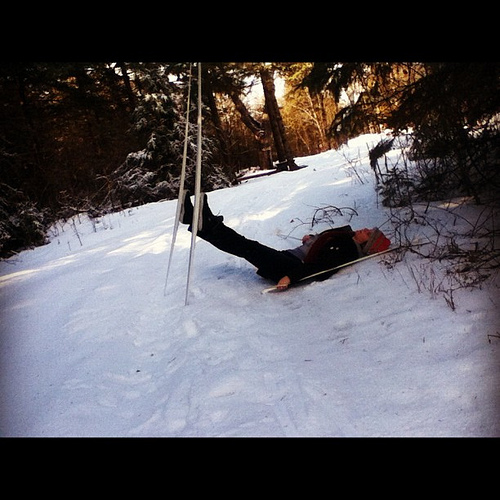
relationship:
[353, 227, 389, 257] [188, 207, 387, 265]
head attached to woman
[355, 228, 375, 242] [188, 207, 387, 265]
face attached to woman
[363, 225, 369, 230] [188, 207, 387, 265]
nose attached to woman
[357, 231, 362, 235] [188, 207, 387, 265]
mouth attached to woman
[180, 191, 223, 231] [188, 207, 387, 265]
boots attached to woman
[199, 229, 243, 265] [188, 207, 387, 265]
legs attached to woman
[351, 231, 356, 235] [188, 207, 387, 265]
chin attached to woman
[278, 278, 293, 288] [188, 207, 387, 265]
hand attached to woman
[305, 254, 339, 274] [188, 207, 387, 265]
arm attached to woman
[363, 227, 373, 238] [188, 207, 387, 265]
eye attached to woman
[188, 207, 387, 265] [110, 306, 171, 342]
woman on top of snow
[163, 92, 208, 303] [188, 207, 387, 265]
skis attached to woman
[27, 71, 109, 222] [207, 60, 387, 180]
tree in forest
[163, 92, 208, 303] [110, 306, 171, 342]
skis on top of snow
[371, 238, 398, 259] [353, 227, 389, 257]
hat on top of head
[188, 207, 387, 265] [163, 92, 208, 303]
woman holding skis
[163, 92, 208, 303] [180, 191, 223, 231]
skis attached to boots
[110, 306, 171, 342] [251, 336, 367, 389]
snow covers ground